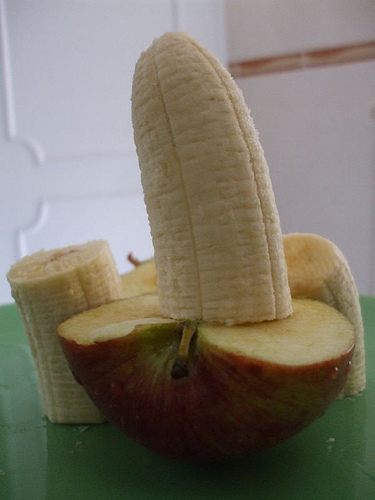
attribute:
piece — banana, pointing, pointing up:
[132, 30, 295, 322]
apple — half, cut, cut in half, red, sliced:
[58, 284, 357, 471]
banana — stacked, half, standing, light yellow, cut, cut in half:
[131, 27, 294, 317]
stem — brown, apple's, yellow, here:
[171, 326, 199, 381]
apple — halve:
[119, 259, 162, 298]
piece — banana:
[7, 236, 124, 440]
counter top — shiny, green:
[1, 292, 374, 493]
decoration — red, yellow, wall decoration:
[223, 34, 374, 89]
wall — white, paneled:
[5, 3, 233, 300]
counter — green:
[6, 290, 374, 492]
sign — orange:
[223, 36, 374, 82]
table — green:
[7, 293, 373, 494]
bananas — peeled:
[8, 28, 371, 432]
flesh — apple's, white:
[58, 282, 353, 363]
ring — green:
[178, 323, 198, 357]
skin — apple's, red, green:
[65, 353, 347, 462]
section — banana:
[10, 238, 126, 435]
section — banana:
[279, 230, 366, 405]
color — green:
[134, 321, 202, 383]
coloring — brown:
[101, 361, 296, 443]